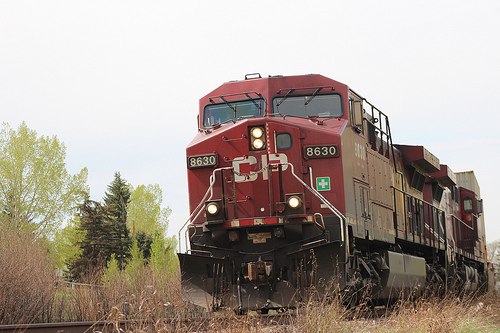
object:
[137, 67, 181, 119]
clouds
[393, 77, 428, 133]
clouds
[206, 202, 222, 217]
light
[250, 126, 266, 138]
light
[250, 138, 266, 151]
light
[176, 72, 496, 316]
train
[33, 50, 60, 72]
skies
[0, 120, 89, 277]
tree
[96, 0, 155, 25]
clouds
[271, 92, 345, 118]
window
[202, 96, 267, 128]
window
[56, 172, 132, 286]
tree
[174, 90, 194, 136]
clouds sky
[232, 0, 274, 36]
clouds sky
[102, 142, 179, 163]
clouds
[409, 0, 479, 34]
clouds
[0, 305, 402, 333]
tracks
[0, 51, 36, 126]
clouds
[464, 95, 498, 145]
clouds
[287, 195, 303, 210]
light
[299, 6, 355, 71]
cloud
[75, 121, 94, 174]
clound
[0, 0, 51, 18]
cloud